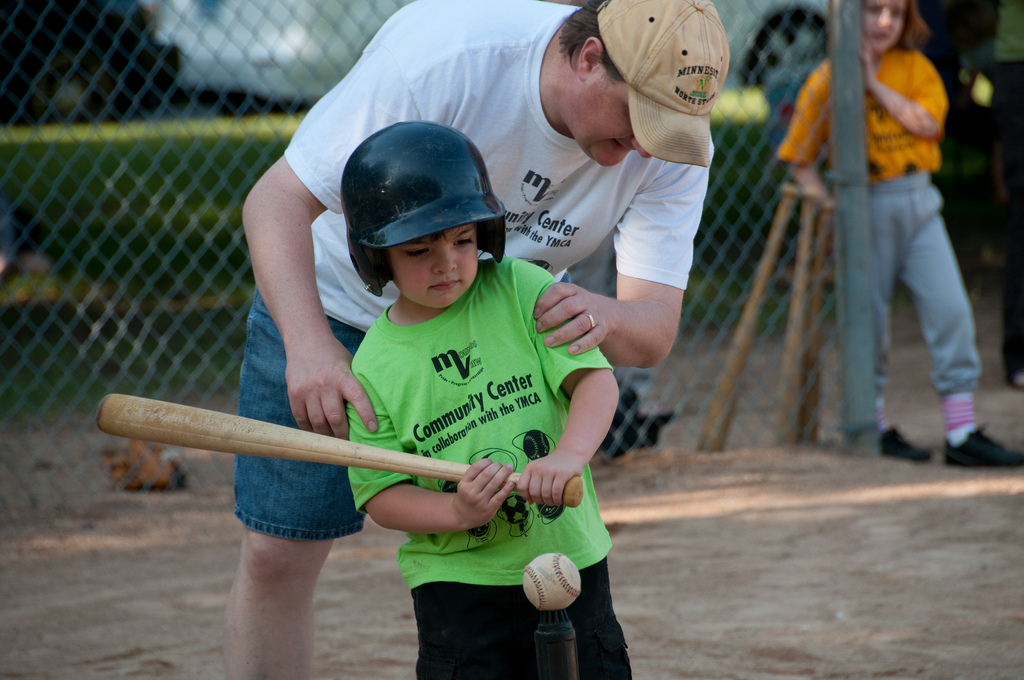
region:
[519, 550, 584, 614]
A baseball on a tee.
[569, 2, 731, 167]
A hat on the man's head.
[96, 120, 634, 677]
A little boy holding a baseball bat.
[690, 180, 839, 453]
Baseball bats leaning against the fence.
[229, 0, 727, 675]
A man helping the young boy with his swing.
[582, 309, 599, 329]
A wedding ring on the man's hand.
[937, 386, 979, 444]
Stripped socks on the player's foot.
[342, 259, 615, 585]
A green shirt on the little boy.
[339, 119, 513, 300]
A batting helmet on the boy's head.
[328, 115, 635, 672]
young boy wearing batter's helmet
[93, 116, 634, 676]
young boy holding baseball bat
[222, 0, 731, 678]
man holding boy's shoulders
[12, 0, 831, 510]
chainlink fence behind man and boy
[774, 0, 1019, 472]
girl with hand on metal pole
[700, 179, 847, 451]
three baseball bats leaning on chainlink fence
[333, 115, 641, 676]
flying baseball is approaching young batter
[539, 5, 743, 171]
baseball cap on man's head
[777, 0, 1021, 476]
girl wearing orange t-shirt and grey sweatpants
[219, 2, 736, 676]
man is wearing denim shorts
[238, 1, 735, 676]
man with brown cap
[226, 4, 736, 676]
man wearing white t-shirt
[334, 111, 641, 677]
child wearing blue baseball hat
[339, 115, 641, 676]
child wearing green t-shirt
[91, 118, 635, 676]
child swing baseball bat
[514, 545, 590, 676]
baseball setting on stand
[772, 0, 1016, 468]
girl with gray pant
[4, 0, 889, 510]
a metal baseball fence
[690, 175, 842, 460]
three baseball bats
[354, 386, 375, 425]
finger on the hand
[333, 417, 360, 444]
finger on the hand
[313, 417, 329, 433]
finger on the hand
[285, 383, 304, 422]
finger on the hand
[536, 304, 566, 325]
finger on the hand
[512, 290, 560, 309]
finger on the hand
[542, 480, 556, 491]
finger on the hand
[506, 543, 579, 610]
White baseball in mid air.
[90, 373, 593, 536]
Brown bat int he little boy's hands.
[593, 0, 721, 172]
Khaki hat on top of the man's head.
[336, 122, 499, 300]
Hard black hat on top of the boys head.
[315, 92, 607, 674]
Little boy about to hit the wall.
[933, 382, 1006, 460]
Red and white sock under the jeans.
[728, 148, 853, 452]
Three baseball bats under girls hands.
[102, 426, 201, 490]
Brown baseball glove in the dirt.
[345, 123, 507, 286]
the helmet is black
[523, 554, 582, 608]
red and white ball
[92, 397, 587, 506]
the bat is brown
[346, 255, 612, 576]
the shirt is green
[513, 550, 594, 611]
a small baseball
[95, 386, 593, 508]
a brown baseball bat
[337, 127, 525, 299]
a black baseball helmet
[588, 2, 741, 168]
a brown baseball cap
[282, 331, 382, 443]
a man's hand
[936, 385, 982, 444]
a girl's red and white sock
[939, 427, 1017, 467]
a girl's black shoe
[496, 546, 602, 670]
Baseball on a tee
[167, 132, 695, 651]
Kid in a green shirt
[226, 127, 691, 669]
Kid holding baseball bat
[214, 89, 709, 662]
Kid in black helmet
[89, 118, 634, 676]
A little boy with his bat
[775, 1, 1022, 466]
A girl in an orange shirt